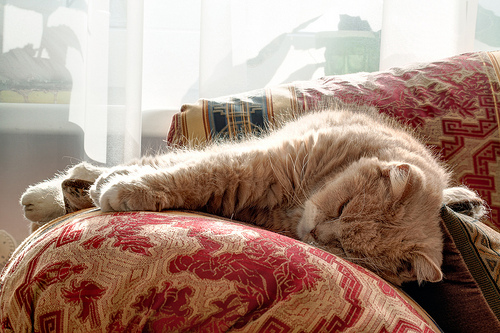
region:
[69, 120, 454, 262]
cat sleeping in sun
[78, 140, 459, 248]
large yellow striped cat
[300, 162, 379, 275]
angry face of cat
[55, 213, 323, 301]
red and tan couch cushion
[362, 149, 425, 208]
right ear of cat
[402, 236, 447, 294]
left ear of cat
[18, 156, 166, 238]
white paws of cat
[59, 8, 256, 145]
sunlight coming through window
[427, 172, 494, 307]
pillow behind sleeping cat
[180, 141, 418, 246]
cat with fluffy yellow fur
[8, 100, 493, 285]
Cat on the sofa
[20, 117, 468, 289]
Cat is sleeping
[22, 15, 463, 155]
Its sunny outside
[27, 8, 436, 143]
Light is reflecting in the room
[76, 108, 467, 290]
Fur is light orange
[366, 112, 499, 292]
Pillow in the corner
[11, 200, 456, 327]
Pattern on sofa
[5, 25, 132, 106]
Item by window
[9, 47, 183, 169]
The room is white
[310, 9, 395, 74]
A plant on seal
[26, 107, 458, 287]
a cat taking a nap on a couch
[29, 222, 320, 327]
an intricately patterned arm rest of a couch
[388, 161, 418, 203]
a cat's ear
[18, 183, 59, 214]
a cat's paw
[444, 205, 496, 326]
a patterned throw pillow on a couch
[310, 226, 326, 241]
a cat's nose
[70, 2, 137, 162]
a sheer curtain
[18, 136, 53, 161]
a wall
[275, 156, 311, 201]
a cat's whiskers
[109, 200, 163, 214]
a cat's claws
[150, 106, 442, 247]
orange cat on sofa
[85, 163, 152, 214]
cat has white paws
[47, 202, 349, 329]
pillow is red and flowered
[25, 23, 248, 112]
white window behind cat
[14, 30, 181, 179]
window has white shades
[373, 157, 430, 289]
cat has brown ears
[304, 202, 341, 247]
cat has brown nose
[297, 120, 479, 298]
cat's head lying down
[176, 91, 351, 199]
blue stripe on sofa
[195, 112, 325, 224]
orange fur on cat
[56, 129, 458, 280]
A cat is sleeping on the couch.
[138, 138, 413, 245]
The cat is brown and white.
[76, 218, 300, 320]
The couch arm has a red pattern.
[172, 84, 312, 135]
The couch has a blue stripes on it.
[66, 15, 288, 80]
The sunlight is shining through the window.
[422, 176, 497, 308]
The cat has his head on the pillow.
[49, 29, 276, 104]
A sheer curtain on the window.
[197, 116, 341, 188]
The cat is hairy.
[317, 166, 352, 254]
The cat eyes are closed.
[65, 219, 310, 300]
The sofa is red and beige.